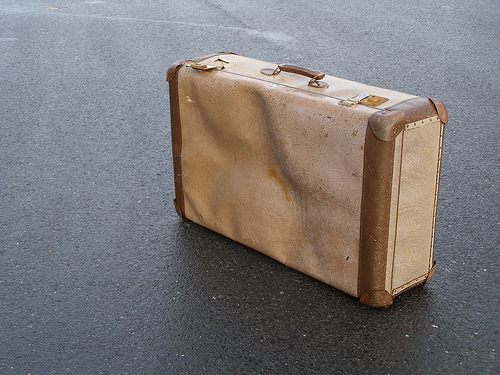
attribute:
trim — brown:
[353, 95, 448, 307]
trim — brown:
[166, 49, 236, 220]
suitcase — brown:
[137, 57, 472, 313]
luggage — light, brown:
[273, 47, 454, 327]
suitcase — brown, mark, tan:
[153, 39, 455, 316]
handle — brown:
[274, 60, 325, 84]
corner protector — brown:
[357, 288, 392, 306]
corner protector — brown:
[369, 108, 405, 140]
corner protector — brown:
[427, 96, 447, 123]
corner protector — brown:
[166, 60, 181, 81]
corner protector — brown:
[425, 260, 435, 279]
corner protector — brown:
[172, 198, 183, 219]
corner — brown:
[168, 197, 184, 219]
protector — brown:
[367, 107, 407, 142]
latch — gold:
[338, 92, 371, 108]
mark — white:
[180, 88, 198, 111]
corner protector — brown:
[432, 98, 447, 122]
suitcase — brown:
[166, 51, 448, 307]